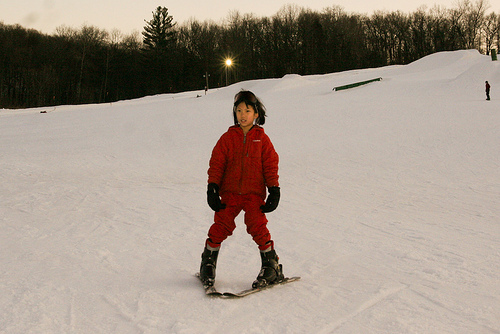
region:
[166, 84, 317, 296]
A little girl skiing.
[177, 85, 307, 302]
A little girl skiing.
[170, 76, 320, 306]
A little girl skiing.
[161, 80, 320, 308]
A little girl skiing.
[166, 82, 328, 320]
A little girl skiing.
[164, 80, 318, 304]
A little girl skiing.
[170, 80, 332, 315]
A little girl skiing.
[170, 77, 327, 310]
A little girl skiing.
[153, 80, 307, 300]
A little girl skiing.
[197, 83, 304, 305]
child in red suit skiing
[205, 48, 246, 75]
sun shining through the trees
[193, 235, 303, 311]
skiis being worn by child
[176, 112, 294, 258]
red snow suit worn by child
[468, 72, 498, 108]
person in background to right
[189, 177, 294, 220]
black gloves worn by child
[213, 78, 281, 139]
face of child in red suit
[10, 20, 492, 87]
tree line behind child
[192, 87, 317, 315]
child in red snow suit and skiis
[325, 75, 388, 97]
log laying in snow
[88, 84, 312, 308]
this is a person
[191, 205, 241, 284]
this is a leg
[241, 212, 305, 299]
this is a leg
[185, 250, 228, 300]
this is a ski board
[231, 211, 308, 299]
this is a ski board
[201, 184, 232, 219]
this is a black glove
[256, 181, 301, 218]
this is a black glove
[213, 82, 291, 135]
this is a head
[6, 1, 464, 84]
this is vegetation in the horizon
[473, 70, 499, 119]
this is a person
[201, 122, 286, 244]
the jacket is red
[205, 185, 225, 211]
the gloves are black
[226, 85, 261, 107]
snow goggles are on the forehead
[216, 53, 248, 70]
sunlight is shining through th trees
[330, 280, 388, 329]
skitracks are on the snow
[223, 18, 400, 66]
trees are in the background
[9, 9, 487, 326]
the photo was taken during the day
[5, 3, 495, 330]
the season is winter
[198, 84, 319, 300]
the smalll kid is asian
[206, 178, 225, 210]
the glove is black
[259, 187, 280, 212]
the glove is black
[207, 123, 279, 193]
the jacket is red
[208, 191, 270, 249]
the pants are red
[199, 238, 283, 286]
the shoes are black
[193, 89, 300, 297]
the child on the skis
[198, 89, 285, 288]
the child has black hair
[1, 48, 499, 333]
the snow is white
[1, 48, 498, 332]
the child standing on the snow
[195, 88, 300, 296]
the child dressed to be out in the snow